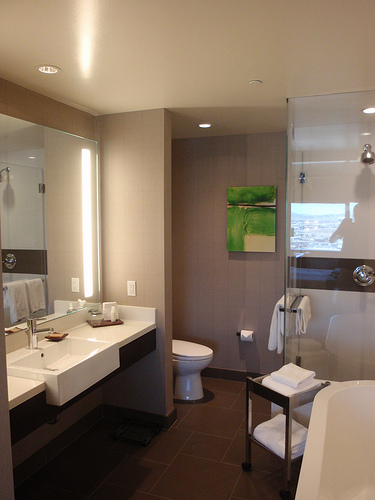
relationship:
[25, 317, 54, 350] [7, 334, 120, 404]
faucet over sink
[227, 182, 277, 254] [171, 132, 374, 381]
picture on wall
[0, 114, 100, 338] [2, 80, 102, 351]
mirror on wall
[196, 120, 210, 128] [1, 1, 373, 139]
light on ceiling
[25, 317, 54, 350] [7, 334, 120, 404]
faucet atop sink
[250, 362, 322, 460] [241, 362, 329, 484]
towels on rack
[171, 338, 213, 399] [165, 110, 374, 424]
toilet in alcove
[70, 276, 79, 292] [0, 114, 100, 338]
electrical outlet reflected in mirror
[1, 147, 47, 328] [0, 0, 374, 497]
shower in bathroom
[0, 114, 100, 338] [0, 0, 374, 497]
mirror in bathroom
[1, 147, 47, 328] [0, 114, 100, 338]
shower reflected in mirror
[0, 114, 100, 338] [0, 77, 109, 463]
mirror on wall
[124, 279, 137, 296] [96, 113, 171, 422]
eletrical outlet on wall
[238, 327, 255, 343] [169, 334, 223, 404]
paper roll near toilet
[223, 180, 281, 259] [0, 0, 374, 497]
picture in bathroom